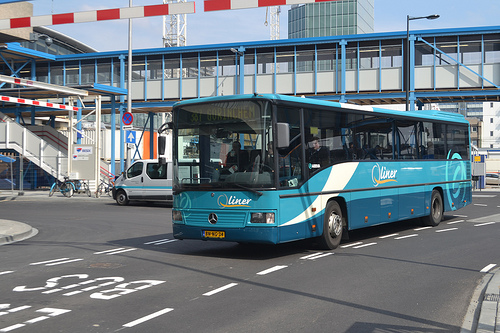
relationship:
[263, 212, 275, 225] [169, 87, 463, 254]
headlight on front of bus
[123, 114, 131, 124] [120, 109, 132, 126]
lines on sign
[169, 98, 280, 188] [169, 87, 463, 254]
window of bus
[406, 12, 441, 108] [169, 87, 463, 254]
lightpole behind bus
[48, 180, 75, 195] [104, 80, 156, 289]
bicycle by pole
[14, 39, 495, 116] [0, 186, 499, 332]
bridge on top road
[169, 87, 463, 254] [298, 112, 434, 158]
bus carrying passengers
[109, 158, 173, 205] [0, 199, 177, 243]
white van parked on street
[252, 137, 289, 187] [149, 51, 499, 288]
driver driving bus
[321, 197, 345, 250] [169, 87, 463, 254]
tire of bus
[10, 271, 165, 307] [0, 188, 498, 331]
word on road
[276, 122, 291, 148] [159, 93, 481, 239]
mirror on bus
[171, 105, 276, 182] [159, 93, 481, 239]
window on bus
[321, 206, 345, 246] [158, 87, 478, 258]
tire of bus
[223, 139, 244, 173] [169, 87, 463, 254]
person sitting on bus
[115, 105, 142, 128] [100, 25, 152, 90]
sign on pole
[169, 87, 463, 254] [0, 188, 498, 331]
bus on road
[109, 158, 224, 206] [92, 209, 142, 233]
white van on road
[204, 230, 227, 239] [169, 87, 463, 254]
plate on bus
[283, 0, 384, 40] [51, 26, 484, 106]
building behind walkway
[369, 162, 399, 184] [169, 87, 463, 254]
word on bus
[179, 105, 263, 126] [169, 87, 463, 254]
number on bus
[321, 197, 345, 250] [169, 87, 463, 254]
tire on bus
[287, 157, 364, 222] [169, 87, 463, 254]
stripe on bus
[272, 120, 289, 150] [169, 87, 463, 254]
mirror on bus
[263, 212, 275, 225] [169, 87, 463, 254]
headlight on bus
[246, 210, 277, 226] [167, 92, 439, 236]
headlight on bus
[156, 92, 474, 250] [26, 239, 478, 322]
bus on road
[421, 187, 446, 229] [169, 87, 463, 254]
back tire of bus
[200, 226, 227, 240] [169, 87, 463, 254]
plate of bus